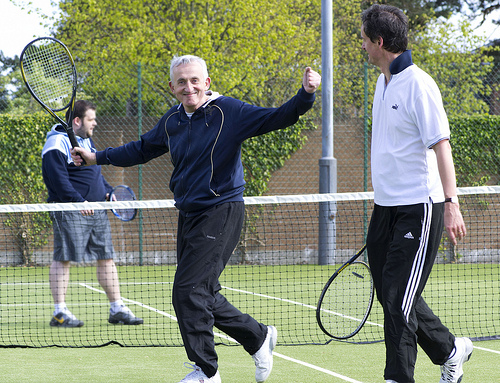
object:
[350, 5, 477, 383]
man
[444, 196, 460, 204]
watch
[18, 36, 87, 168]
tennis racket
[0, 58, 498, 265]
fence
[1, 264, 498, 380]
tennis court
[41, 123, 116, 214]
sweatshirt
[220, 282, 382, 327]
lines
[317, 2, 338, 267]
post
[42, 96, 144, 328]
man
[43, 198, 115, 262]
shorts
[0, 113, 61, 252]
ivy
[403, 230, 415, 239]
adidas logo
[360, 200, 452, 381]
man's pants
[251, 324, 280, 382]
white shoes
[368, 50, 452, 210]
shirt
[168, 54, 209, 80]
hair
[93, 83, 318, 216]
jacket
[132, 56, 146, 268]
post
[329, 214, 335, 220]
bolt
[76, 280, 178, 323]
lines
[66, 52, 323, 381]
man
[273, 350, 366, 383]
line